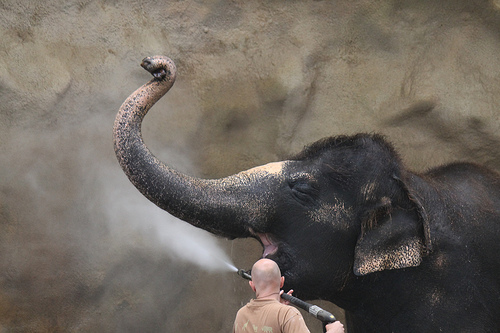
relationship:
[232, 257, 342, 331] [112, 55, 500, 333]
guy washing elephant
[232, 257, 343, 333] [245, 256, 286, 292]
guy  bald headed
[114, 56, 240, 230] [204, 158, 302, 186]
trunk has a patch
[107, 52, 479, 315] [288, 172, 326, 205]
elephant has eyes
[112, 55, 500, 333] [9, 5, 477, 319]
elephant in zoo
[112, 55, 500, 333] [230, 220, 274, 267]
elephant opening its mouth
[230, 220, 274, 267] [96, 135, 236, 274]
mouth for water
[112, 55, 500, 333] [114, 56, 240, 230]
elephant curving its trunk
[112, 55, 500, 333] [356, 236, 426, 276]
elephant has discoloration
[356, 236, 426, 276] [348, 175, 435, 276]
discoloration on its ear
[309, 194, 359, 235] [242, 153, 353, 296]
discoloration on face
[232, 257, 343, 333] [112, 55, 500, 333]
guy sprays elephant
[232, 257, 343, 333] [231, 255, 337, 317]
guy uses a hose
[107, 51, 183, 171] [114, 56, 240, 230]
end of trunk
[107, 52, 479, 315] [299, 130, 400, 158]
elephant has hair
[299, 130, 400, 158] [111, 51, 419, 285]
hair on its head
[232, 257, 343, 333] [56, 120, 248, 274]
guy spraying water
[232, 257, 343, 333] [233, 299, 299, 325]
guy wearing a t shirt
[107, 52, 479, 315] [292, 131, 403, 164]
elephant has hair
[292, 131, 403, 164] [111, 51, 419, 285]
hair on its head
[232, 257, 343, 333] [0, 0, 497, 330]
guy spraying wall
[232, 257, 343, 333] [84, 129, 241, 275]
guy spraying water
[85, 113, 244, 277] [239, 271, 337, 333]
water spraying from hose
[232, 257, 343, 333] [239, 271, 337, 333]
guy holding hose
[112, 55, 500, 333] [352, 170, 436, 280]
elephant has ear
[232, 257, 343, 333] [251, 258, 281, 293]
guy has bald headed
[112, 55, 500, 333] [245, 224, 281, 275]
elephant has mouth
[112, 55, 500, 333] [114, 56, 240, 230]
elephant has trunk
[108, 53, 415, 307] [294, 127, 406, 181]
head has hair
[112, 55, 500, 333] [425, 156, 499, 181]
elephant has hump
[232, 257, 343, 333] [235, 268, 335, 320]
guy holding hose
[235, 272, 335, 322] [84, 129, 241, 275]
hose spraying water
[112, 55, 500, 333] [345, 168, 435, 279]
elephant has ear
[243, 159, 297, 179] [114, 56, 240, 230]
spot on trunk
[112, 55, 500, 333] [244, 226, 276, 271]
elephant has mouth